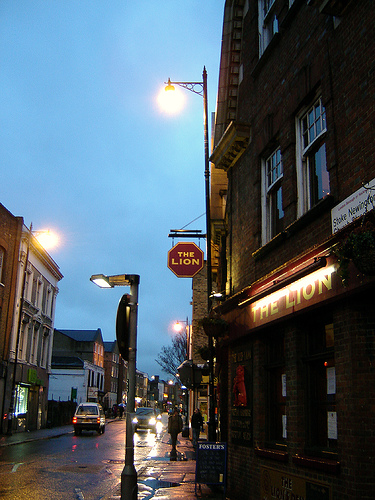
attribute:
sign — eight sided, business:
[165, 239, 207, 281]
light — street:
[84, 266, 143, 493]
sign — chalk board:
[191, 438, 231, 491]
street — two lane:
[2, 407, 200, 498]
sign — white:
[325, 176, 374, 242]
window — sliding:
[294, 80, 347, 215]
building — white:
[48, 356, 107, 425]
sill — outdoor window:
[291, 445, 346, 473]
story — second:
[211, 31, 374, 295]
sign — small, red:
[162, 237, 204, 279]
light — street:
[88, 263, 150, 496]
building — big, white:
[53, 325, 104, 413]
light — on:
[152, 80, 190, 120]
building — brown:
[201, 0, 371, 496]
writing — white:
[195, 445, 224, 450]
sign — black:
[195, 440, 226, 475]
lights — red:
[72, 416, 104, 425]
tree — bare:
[156, 328, 187, 374]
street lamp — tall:
[5, 223, 67, 430]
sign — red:
[167, 242, 203, 278]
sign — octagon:
[167, 240, 205, 280]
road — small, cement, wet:
[0, 415, 169, 498]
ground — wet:
[2, 417, 220, 497]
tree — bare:
[152, 317, 189, 402]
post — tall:
[199, 63, 220, 458]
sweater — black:
[186, 412, 206, 431]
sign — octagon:
[163, 238, 208, 283]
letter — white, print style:
[258, 302, 270, 318]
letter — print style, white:
[267, 295, 280, 313]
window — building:
[22, 261, 33, 303]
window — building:
[22, 263, 36, 297]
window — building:
[24, 267, 36, 301]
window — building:
[24, 265, 34, 300]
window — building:
[27, 264, 33, 301]